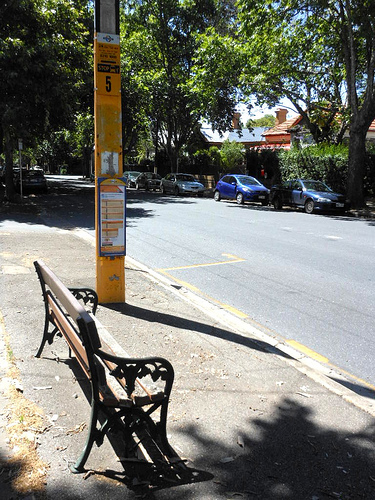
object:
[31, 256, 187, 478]
bench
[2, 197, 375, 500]
sidewalk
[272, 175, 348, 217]
car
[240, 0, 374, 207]
tree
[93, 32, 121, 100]
sign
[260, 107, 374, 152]
house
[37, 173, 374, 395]
road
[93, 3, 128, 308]
pole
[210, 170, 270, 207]
car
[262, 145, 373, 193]
bush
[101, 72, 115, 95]
number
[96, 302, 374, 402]
shadow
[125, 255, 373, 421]
curb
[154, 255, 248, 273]
line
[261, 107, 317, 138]
roof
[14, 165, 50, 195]
car